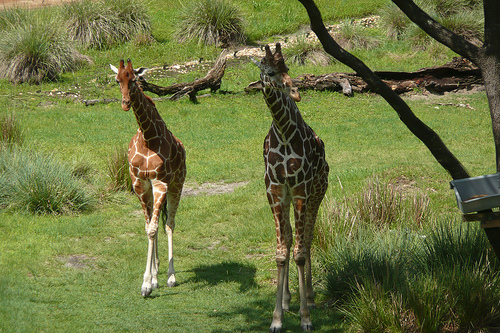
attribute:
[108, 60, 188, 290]
giraffe — looking ahead, walking, tall, looking forward, brown, spotted, white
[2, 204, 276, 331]
grass — green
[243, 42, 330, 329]
giraffe — brown, white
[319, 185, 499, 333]
grass — green, tall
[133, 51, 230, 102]
log — dead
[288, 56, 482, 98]
log — dried up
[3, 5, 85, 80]
shrub — green, spiky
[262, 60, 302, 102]
face — narrow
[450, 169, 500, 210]
box — white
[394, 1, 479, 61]
branch — bare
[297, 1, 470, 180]
branch — bare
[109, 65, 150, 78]
ears — white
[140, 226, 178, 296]
legs — white